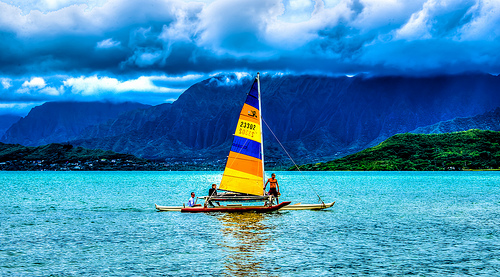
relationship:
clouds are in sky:
[10, 0, 491, 58] [3, 2, 498, 100]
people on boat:
[183, 165, 280, 208] [154, 73, 335, 214]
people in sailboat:
[209, 184, 218, 196] [118, 64, 353, 219]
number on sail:
[237, 118, 259, 131] [208, 64, 278, 214]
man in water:
[263, 173, 279, 206] [159, 211, 419, 264]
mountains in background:
[28, 25, 498, 215] [287, 72, 456, 147]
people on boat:
[209, 184, 218, 196] [177, 201, 287, 213]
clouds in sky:
[0, 0, 500, 74] [0, 0, 498, 119]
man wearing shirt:
[262, 171, 280, 203] [205, 188, 219, 202]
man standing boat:
[263, 173, 279, 206] [154, 73, 335, 214]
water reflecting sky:
[1, 167, 496, 271] [3, 2, 498, 100]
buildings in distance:
[26, 156, 54, 174] [45, 124, 203, 153]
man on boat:
[263, 170, 282, 207] [154, 73, 335, 214]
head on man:
[270, 171, 275, 182] [262, 175, 280, 204]